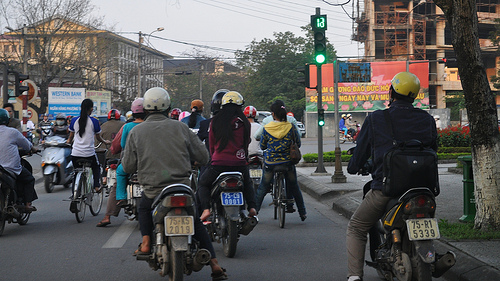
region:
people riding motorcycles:
[111, 50, 455, 275]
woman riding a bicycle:
[248, 93, 304, 243]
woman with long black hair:
[53, 97, 115, 225]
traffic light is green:
[291, 4, 347, 187]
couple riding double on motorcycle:
[193, 83, 260, 255]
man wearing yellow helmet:
[369, 60, 441, 112]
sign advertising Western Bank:
[38, 72, 114, 142]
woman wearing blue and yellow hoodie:
[258, 95, 305, 177]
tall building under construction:
[352, 6, 462, 116]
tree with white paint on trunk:
[428, 9, 497, 247]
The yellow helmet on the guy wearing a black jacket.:
[390, 72, 422, 97]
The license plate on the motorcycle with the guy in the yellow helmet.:
[406, 217, 439, 240]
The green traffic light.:
[312, 51, 325, 66]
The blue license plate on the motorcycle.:
[213, 187, 245, 204]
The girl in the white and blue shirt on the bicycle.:
[64, 98, 112, 218]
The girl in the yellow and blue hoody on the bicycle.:
[258, 98, 309, 223]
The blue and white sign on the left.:
[37, 80, 89, 115]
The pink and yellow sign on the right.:
[303, 60, 431, 108]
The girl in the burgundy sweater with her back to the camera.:
[207, 90, 265, 230]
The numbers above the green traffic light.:
[307, 16, 325, 28]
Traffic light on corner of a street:
[304, 4, 335, 179]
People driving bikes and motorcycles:
[1, 62, 451, 274]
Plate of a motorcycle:
[395, 207, 445, 243]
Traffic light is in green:
[303, 3, 339, 188]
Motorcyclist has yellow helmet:
[334, 64, 447, 279]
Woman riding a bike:
[256, 93, 314, 238]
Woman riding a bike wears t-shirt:
[53, 94, 115, 228]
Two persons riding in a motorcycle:
[201, 81, 266, 267]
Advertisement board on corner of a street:
[303, 48, 439, 116]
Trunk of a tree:
[442, 3, 498, 237]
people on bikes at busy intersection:
[22, 60, 458, 255]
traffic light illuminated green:
[301, 7, 336, 182]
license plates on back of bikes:
[146, 180, 441, 247]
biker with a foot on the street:
[120, 85, 236, 280]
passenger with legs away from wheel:
[237, 95, 317, 230]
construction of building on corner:
[337, 6, 492, 162]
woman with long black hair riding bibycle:
[60, 90, 110, 220]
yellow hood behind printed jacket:
[251, 92, 302, 177]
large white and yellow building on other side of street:
[5, 10, 171, 120]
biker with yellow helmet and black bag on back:
[310, 55, 476, 268]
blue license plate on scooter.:
[218, 189, 250, 205]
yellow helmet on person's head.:
[388, 69, 427, 104]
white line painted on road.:
[109, 223, 130, 250]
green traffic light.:
[306, 29, 327, 66]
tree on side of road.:
[445, 11, 492, 188]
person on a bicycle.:
[67, 100, 101, 201]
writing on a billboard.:
[340, 72, 392, 109]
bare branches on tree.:
[19, 8, 84, 72]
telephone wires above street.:
[241, 4, 308, 20]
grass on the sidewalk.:
[451, 217, 466, 234]